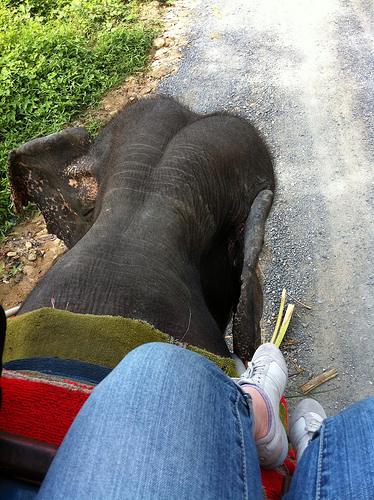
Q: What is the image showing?
A: It is showing a road.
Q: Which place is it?
A: It is a road.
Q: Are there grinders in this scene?
A: No, there are no grinders.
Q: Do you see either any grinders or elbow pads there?
A: No, there are no grinders or elbow pads.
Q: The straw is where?
A: The straw is on the road.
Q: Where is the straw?
A: The straw is on the road.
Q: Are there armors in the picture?
A: No, there are no armors.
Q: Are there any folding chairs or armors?
A: No, there are no armors or folding chairs.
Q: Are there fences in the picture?
A: No, there are no fences.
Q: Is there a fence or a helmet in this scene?
A: No, there are no fences or helmets.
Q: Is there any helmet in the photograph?
A: No, there are no helmets.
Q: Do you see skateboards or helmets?
A: No, there are no helmets or skateboards.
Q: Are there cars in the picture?
A: No, there are no cars.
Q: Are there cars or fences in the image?
A: No, there are no cars or fences.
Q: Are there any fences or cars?
A: No, there are no cars or fences.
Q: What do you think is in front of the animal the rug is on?
A: The road is in front of the elephant.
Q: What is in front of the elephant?
A: The road is in front of the elephant.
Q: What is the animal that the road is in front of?
A: The animal is an elephant.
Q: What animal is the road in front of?
A: The road is in front of the elephant.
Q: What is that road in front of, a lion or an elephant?
A: The road is in front of an elephant.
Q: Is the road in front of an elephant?
A: Yes, the road is in front of an elephant.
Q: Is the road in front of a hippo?
A: No, the road is in front of an elephant.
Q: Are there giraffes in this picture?
A: No, there are no giraffes.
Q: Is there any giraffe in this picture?
A: No, there are no giraffes.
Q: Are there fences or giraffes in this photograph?
A: No, there are no giraffes or fences.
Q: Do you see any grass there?
A: Yes, there is grass.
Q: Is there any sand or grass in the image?
A: Yes, there is grass.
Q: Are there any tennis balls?
A: No, there are no tennis balls.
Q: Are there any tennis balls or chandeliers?
A: No, there are no tennis balls or chandeliers.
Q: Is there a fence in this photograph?
A: No, there are no fences.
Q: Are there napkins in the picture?
A: No, there are no napkins.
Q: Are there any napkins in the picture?
A: No, there are no napkins.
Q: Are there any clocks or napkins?
A: No, there are no napkins or clocks.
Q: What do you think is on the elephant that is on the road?
A: The rug is on the elephant.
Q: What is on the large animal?
A: The rug is on the elephant.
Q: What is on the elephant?
A: The rug is on the elephant.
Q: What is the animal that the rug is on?
A: The animal is an elephant.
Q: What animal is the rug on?
A: The rug is on the elephant.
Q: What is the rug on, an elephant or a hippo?
A: The rug is on an elephant.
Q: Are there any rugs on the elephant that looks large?
A: Yes, there is a rug on the elephant.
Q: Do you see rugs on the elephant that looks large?
A: Yes, there is a rug on the elephant.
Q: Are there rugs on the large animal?
A: Yes, there is a rug on the elephant.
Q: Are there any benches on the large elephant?
A: No, there is a rug on the elephant.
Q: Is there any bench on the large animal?
A: No, there is a rug on the elephant.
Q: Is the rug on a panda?
A: No, the rug is on the elephant.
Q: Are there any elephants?
A: Yes, there is an elephant.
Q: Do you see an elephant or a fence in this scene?
A: Yes, there is an elephant.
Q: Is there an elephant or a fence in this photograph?
A: Yes, there is an elephant.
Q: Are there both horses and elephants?
A: No, there is an elephant but no horses.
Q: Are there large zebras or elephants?
A: Yes, there is a large elephant.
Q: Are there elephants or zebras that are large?
A: Yes, the elephant is large.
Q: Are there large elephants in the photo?
A: Yes, there is a large elephant.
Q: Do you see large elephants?
A: Yes, there is a large elephant.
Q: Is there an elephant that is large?
A: Yes, there is an elephant that is large.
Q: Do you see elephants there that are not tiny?
A: Yes, there is a large elephant.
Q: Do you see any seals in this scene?
A: No, there are no seals.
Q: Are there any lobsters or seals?
A: No, there are no seals or lobsters.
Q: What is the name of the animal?
A: The animal is an elephant.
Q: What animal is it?
A: The animal is an elephant.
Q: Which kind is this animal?
A: This is an elephant.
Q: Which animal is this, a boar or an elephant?
A: This is an elephant.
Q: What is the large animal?
A: The animal is an elephant.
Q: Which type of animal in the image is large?
A: The animal is an elephant.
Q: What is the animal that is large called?
A: The animal is an elephant.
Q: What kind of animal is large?
A: The animal is an elephant.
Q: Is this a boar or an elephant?
A: This is an elephant.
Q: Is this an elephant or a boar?
A: This is an elephant.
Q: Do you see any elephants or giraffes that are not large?
A: No, there is an elephant but it is large.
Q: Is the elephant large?
A: Yes, the elephant is large.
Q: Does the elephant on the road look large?
A: Yes, the elephant is large.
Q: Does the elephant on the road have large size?
A: Yes, the elephant is large.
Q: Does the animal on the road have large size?
A: Yes, the elephant is large.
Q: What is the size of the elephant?
A: The elephant is large.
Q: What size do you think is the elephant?
A: The elephant is large.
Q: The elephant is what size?
A: The elephant is large.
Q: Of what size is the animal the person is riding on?
A: The elephant is large.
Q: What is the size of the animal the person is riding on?
A: The elephant is large.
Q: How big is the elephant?
A: The elephant is large.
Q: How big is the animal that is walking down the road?
A: The elephant is large.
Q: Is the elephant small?
A: No, the elephant is large.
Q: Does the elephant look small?
A: No, the elephant is large.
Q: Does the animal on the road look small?
A: No, the elephant is large.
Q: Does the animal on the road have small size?
A: No, the elephant is large.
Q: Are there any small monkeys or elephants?
A: No, there is an elephant but it is large.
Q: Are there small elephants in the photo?
A: No, there is an elephant but it is large.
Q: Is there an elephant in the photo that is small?
A: No, there is an elephant but it is large.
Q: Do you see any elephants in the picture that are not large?
A: No, there is an elephant but it is large.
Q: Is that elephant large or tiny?
A: The elephant is large.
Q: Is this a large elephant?
A: Yes, this is a large elephant.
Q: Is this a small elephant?
A: No, this is a large elephant.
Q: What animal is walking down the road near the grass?
A: The elephant is walking down the road.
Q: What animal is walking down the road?
A: The elephant is walking down the road.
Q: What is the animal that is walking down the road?
A: The animal is an elephant.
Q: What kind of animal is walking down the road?
A: The animal is an elephant.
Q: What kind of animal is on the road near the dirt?
A: The animal is an elephant.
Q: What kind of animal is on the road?
A: The animal is an elephant.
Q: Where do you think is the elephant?
A: The elephant is on the road.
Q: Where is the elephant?
A: The elephant is on the road.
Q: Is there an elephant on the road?
A: Yes, there is an elephant on the road.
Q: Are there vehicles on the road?
A: No, there is an elephant on the road.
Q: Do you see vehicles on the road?
A: No, there is an elephant on the road.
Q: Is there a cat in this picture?
A: No, there are no cats.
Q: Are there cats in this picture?
A: No, there are no cats.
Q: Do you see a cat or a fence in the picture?
A: No, there are no cats or fences.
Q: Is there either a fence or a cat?
A: No, there are no cats or fences.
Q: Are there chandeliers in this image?
A: No, there are no chandeliers.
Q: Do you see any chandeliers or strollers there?
A: No, there are no chandeliers or strollers.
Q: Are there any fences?
A: No, there are no fences.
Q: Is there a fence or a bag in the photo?
A: No, there are no fences or bags.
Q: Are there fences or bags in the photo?
A: No, there are no fences or bags.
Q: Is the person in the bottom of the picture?
A: Yes, the person is in the bottom of the image.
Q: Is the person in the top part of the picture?
A: No, the person is in the bottom of the image.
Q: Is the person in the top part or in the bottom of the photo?
A: The person is in the bottom of the image.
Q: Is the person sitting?
A: Yes, the person is sitting.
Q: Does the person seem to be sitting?
A: Yes, the person is sitting.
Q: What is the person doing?
A: The person is sitting.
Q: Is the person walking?
A: No, the person is sitting.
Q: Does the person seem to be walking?
A: No, the person is sitting.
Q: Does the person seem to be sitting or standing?
A: The person is sitting.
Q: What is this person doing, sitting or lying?
A: The person is sitting.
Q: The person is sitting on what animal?
A: The person is sitting on the elephant.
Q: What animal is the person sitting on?
A: The person is sitting on the elephant.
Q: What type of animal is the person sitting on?
A: The person is sitting on the elephant.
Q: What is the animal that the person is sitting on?
A: The animal is an elephant.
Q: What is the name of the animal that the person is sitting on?
A: The animal is an elephant.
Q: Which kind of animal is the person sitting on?
A: The person is sitting on the elephant.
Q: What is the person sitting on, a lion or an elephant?
A: The person is sitting on an elephant.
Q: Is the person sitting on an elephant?
A: Yes, the person is sitting on an elephant.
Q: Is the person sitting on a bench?
A: No, the person is sitting on an elephant.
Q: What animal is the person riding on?
A: The person is riding on an elephant.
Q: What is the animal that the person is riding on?
A: The animal is an elephant.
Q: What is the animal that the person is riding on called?
A: The animal is an elephant.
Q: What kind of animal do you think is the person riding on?
A: The person is riding on an elephant.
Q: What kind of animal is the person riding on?
A: The person is riding on an elephant.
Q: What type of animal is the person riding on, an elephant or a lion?
A: The person is riding on an elephant.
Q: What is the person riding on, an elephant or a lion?
A: The person is riding on an elephant.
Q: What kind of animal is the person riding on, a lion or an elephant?
A: The person is riding on an elephant.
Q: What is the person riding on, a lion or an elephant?
A: The person is riding on an elephant.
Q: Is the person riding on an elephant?
A: Yes, the person is riding on an elephant.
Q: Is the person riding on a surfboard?
A: No, the person is riding on an elephant.